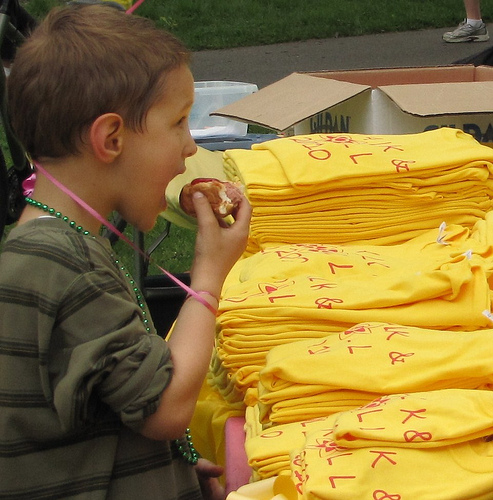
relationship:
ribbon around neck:
[65, 194, 212, 317] [34, 166, 109, 237]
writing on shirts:
[291, 243, 391, 311] [203, 142, 483, 490]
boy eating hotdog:
[17, 17, 257, 447] [184, 179, 246, 224]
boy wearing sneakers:
[0, 0, 244, 500] [433, 24, 492, 51]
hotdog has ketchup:
[184, 179, 246, 224] [190, 175, 213, 186]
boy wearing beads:
[17, 17, 257, 447] [35, 213, 162, 311]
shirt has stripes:
[4, 229, 180, 500] [7, 240, 111, 277]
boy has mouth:
[17, 17, 257, 447] [163, 165, 190, 208]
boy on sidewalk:
[0, 0, 244, 500] [183, 38, 487, 87]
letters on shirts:
[296, 134, 338, 179] [203, 142, 483, 490]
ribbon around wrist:
[65, 194, 212, 317] [174, 274, 224, 323]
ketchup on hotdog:
[190, 175, 213, 186] [184, 179, 246, 224]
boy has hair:
[17, 17, 257, 447] [26, 31, 148, 112]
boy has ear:
[17, 17, 257, 447] [91, 111, 126, 167]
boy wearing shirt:
[17, 17, 257, 447] [4, 229, 180, 500]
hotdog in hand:
[184, 179, 246, 224] [187, 200, 250, 292]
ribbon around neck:
[20, 160, 217, 320] [34, 166, 109, 237]